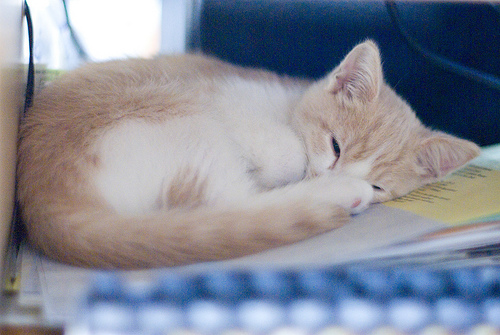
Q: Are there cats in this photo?
A: Yes, there is a cat.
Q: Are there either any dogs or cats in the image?
A: Yes, there is a cat.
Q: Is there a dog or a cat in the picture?
A: Yes, there is a cat.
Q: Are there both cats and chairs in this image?
A: No, there is a cat but no chairs.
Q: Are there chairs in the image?
A: No, there are no chairs.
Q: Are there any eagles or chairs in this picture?
A: No, there are no chairs or eagles.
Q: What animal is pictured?
A: The animal is a cat.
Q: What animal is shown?
A: The animal is a cat.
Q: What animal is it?
A: The animal is a cat.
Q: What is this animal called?
A: This is a cat.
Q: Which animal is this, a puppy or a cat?
A: This is a cat.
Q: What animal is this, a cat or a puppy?
A: This is a cat.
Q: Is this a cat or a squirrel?
A: This is a cat.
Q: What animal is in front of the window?
A: The cat is in front of the window.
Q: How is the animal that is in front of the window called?
A: The animal is a cat.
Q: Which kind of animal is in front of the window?
A: The animal is a cat.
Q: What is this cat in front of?
A: The cat is in front of the window.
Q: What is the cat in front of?
A: The cat is in front of the window.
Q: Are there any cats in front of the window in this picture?
A: Yes, there is a cat in front of the window.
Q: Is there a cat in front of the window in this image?
A: Yes, there is a cat in front of the window.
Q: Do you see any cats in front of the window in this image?
A: Yes, there is a cat in front of the window.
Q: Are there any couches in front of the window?
A: No, there is a cat in front of the window.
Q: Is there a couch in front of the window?
A: No, there is a cat in front of the window.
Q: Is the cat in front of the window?
A: Yes, the cat is in front of the window.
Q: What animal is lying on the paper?
A: The cat is lying on the paper.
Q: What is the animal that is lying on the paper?
A: The animal is a cat.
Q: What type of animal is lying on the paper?
A: The animal is a cat.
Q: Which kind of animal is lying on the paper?
A: The animal is a cat.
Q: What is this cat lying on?
A: The cat is lying on the paper.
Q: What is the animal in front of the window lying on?
A: The cat is lying on the paper.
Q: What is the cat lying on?
A: The cat is lying on the paper.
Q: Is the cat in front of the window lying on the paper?
A: Yes, the cat is lying on the paper.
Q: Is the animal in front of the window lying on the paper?
A: Yes, the cat is lying on the paper.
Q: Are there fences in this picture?
A: No, there are no fences.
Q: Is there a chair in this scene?
A: No, there are no chairs.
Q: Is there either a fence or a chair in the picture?
A: No, there are no chairs or fences.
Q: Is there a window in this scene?
A: Yes, there is a window.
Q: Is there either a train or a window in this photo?
A: Yes, there is a window.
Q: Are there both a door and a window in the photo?
A: No, there is a window but no doors.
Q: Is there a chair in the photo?
A: No, there are no chairs.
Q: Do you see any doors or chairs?
A: No, there are no chairs or doors.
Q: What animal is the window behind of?
A: The window is behind the cat.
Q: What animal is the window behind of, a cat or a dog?
A: The window is behind a cat.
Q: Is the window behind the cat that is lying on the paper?
A: Yes, the window is behind the cat.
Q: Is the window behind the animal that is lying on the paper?
A: Yes, the window is behind the cat.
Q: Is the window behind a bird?
A: No, the window is behind the cat.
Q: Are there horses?
A: No, there are no horses.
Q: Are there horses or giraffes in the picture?
A: No, there are no horses or giraffes.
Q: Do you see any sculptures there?
A: No, there are no sculptures.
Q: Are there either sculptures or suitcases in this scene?
A: No, there are no sculptures or suitcases.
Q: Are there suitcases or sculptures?
A: No, there are no sculptures or suitcases.